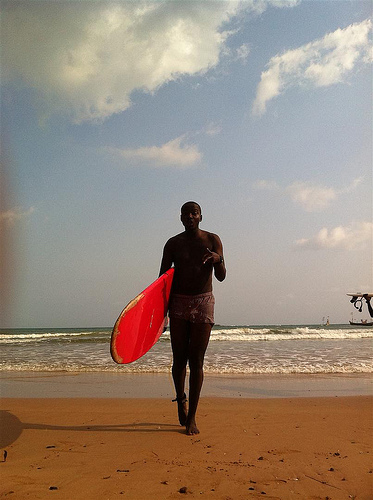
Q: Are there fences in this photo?
A: No, there are no fences.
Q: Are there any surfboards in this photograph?
A: Yes, there is a surfboard.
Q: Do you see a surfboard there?
A: Yes, there is a surfboard.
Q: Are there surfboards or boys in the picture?
A: Yes, there is a surfboard.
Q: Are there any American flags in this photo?
A: No, there are no American flags.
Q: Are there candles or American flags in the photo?
A: No, there are no American flags or candles.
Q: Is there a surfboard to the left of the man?
A: Yes, there is a surfboard to the left of the man.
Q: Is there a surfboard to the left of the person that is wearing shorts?
A: Yes, there is a surfboard to the left of the man.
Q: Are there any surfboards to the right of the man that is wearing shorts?
A: No, the surfboard is to the left of the man.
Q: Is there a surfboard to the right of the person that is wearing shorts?
A: No, the surfboard is to the left of the man.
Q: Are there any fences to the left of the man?
A: No, there is a surfboard to the left of the man.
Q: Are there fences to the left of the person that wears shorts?
A: No, there is a surfboard to the left of the man.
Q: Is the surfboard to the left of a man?
A: Yes, the surfboard is to the left of a man.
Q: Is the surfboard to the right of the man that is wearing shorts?
A: No, the surfboard is to the left of the man.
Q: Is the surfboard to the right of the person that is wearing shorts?
A: No, the surfboard is to the left of the man.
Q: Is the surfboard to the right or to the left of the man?
A: The surfboard is to the left of the man.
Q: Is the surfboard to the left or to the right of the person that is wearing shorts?
A: The surfboard is to the left of the man.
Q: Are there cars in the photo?
A: No, there are no cars.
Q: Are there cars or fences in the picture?
A: No, there are no cars or fences.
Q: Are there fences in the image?
A: No, there are no fences.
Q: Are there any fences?
A: No, there are no fences.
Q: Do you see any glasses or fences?
A: No, there are no fences or glasses.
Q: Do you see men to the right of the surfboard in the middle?
A: Yes, there is a man to the right of the surf board.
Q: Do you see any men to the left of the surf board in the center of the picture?
A: No, the man is to the right of the surfboard.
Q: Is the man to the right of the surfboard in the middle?
A: Yes, the man is to the right of the surfboard.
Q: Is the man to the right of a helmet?
A: No, the man is to the right of the surfboard.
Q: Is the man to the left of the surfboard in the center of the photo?
A: No, the man is to the right of the surf board.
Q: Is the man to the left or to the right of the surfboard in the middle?
A: The man is to the right of the surfboard.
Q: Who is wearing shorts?
A: The man is wearing shorts.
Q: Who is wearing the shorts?
A: The man is wearing shorts.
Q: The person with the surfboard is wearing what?
A: The man is wearing shorts.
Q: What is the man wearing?
A: The man is wearing shorts.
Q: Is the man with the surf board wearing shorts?
A: Yes, the man is wearing shorts.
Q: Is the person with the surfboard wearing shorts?
A: Yes, the man is wearing shorts.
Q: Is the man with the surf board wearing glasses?
A: No, the man is wearing shorts.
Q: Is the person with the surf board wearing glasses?
A: No, the man is wearing shorts.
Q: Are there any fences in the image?
A: No, there are no fences.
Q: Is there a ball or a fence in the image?
A: No, there are no fences or balls.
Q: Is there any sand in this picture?
A: Yes, there is sand.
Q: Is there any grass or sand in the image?
A: Yes, there is sand.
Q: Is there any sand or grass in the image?
A: Yes, there is sand.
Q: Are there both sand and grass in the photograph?
A: No, there is sand but no grass.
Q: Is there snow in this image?
A: No, there is no snow.